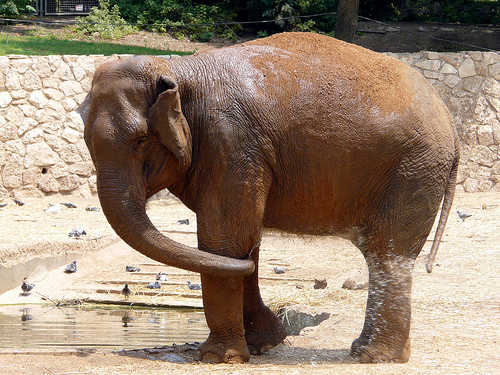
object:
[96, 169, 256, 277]
trunk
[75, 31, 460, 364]
elephant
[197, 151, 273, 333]
front legs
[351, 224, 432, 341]
back legs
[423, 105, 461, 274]
tail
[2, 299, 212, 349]
water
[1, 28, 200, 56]
grass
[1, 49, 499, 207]
wall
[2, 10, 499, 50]
rope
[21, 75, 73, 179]
rock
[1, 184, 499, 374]
ground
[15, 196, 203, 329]
pigeons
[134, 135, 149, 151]
eye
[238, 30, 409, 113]
dirt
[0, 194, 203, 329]
birds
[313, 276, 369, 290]
rocks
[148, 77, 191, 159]
ear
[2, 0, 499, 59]
background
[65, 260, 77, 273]
bird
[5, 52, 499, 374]
enclosure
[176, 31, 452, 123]
back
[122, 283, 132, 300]
bird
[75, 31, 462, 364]
animal